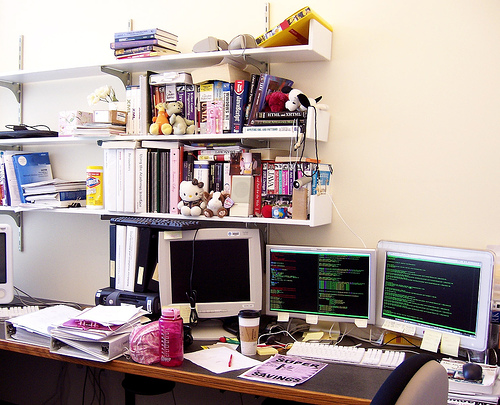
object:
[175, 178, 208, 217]
kitty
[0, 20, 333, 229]
bookshelf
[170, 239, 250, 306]
screen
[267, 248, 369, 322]
screen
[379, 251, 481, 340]
screen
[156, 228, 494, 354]
row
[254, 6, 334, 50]
box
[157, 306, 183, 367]
bottle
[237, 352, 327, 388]
ad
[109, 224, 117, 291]
binders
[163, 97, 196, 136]
animals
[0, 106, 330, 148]
shelf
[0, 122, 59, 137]
shoes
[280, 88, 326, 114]
toy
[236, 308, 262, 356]
cup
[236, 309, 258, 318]
lid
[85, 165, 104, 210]
container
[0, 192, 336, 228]
shelf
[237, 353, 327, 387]
paper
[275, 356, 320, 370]
super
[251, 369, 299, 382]
savings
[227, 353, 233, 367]
pen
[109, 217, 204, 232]
keyboard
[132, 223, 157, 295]
binders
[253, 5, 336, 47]
book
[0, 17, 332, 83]
shelf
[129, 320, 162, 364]
case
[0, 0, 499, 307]
wall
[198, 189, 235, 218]
animal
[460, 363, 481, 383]
mouse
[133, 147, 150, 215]
notebooks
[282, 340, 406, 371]
keyboard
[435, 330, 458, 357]
note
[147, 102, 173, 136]
pets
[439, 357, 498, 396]
books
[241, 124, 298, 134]
book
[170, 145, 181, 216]
binders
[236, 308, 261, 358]
drink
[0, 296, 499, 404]
table